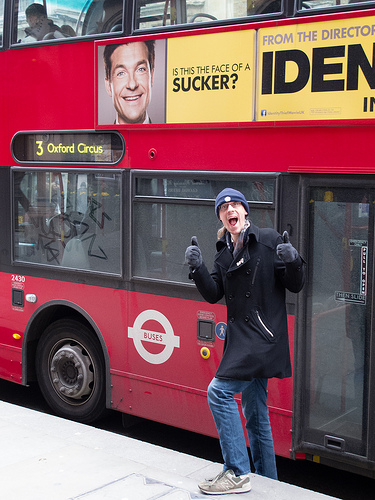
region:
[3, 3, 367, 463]
red double decker bus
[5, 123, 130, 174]
digital information sign on bus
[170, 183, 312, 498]
happy man in black coat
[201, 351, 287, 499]
men's blue denim jeans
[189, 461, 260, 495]
men's brown and white foot wear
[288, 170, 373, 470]
glass entry door on bus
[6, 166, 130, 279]
graffiti in dust on bus window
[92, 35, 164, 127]
comedic actor jason bateman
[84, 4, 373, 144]
movie ad on bus side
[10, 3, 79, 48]
passenger on upper level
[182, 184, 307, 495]
happy man giving two thumbs up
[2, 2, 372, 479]
a big red two story bus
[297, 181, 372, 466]
a sliding glass door on a bus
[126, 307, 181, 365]
a red and white bus sign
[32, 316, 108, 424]
a black tire with a grey hubcap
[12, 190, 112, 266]
strange drawings on a dusty window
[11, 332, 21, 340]
a small yellow reflective button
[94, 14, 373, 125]
a advertisement sign on the side of a bus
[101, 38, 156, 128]
a smiling mans face with blue eyes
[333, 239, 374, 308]
instructive signs on a bus door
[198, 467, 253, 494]
a man's tennis shoe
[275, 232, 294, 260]
a blue glove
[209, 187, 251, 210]
a blue cap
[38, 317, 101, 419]
the tire of a bus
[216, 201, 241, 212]
a man's eyeglasses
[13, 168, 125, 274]
the window of a bus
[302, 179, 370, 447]
the door of a bus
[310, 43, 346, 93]
a capital black letter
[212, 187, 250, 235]
the head of a man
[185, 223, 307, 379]
a man's black coat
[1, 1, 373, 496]
Man exiting city bus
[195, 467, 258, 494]
Men's White and Grey Sneakers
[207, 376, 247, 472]
Men's Left Denim Blue Jean Leg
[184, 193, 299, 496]
Man Exiting City Bus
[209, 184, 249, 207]
Dark Blue Men's Skull Cap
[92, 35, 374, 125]
Advertisement on side of city bus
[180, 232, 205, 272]
Right Hand Man's Glove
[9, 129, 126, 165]
Destination Sign on City Bus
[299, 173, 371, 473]
City Bus Closed Door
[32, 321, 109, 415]
City Bus Tire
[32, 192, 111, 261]
Writing on dirty bus window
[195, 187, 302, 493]
Man wearing black coat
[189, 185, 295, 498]
Man wearing blue jeans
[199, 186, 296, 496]
Man wearing blue ski hat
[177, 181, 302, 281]
Man with gloves giving thumbs up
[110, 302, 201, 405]
The bus is red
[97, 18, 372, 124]
Bus ad is yellow with black writing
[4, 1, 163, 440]
Red double decker bus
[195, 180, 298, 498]
Man with white tennis shoes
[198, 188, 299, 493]
Man wearing winter attire